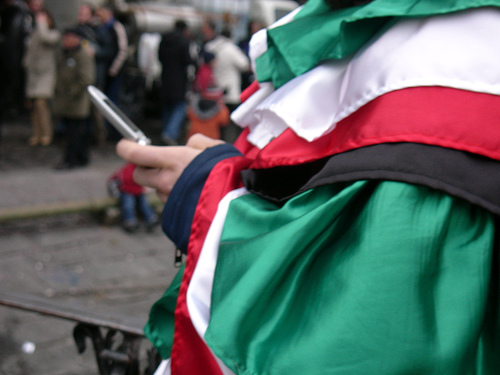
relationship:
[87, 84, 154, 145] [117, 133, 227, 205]
phone in hand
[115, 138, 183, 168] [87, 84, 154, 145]
index finger next to phone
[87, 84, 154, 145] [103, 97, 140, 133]
phone has screen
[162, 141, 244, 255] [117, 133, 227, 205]
sleeve next to hand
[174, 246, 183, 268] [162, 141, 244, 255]
zipper pull below sleeve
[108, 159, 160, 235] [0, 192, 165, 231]
person sitting on curb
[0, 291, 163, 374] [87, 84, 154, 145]
railing beneath phone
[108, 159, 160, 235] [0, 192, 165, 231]
person sits on curb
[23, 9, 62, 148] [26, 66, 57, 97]
lady wearing skirt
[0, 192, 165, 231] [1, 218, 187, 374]
curb along road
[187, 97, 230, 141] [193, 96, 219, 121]
jacket has hood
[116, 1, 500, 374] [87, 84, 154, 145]
person holding phone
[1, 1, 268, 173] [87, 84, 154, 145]
crowd behind phone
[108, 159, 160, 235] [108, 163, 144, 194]
person has shirt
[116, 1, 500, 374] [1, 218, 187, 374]
person on road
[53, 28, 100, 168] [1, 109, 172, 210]
person on sidewalk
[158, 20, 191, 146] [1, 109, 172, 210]
person on sidewalk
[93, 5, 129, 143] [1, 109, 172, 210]
person on sidewalk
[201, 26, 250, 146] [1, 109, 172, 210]
person on sidewalk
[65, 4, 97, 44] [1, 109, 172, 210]
person on sidewalk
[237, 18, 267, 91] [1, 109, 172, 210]
person on sidewalk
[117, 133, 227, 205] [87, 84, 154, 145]
hand holding phone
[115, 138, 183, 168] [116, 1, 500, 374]
index finger of person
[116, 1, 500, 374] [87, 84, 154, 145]
person using phone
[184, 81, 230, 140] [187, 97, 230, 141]
person has jacket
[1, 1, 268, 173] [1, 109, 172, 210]
crowd standing on sidewalk